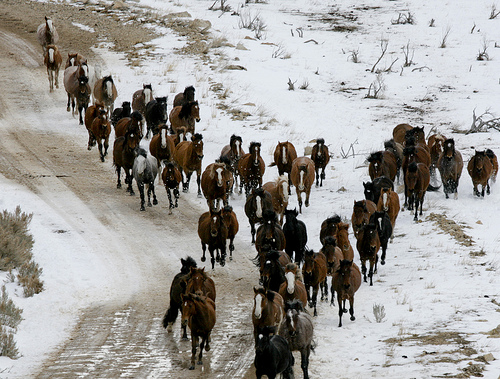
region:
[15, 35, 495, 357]
The horses are running in the snow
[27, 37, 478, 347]
The horses are frightened by something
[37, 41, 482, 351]
Many horses are running together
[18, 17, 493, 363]
The horses are ready to stampede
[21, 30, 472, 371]
Wild horses are running down a mountain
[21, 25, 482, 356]
Wild horses are in the snow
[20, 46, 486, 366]
Stallions and mares are running together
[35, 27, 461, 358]
Wild horses are running free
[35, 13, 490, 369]
Snow is covering the ground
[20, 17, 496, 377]
a herd of horses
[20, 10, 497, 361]
the horses are running in the snow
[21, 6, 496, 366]
a large herd of wild horses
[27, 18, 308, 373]
many of these horses have white faces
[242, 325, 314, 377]
this horse is black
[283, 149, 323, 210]
this horse is very fat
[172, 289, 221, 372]
this horse is brown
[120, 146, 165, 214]
this horse is ashen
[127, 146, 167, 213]
this horse is grey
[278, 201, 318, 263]
this horse is very black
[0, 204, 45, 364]
Scrubby bushes in snow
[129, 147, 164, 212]
Grey horse running with brown horses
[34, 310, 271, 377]
Muddy path worn by horse hooves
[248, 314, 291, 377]
Dark colored horse with white face spot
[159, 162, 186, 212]
Little brown horse running in snow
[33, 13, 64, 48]
Light colored horse at the rear of the group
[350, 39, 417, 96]
Dead branches in the snow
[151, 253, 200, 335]
Backwards facing horse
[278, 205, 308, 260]
Solid dark colored horse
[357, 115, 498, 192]
Small grouping of horses running in the snow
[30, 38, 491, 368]
Horses are running together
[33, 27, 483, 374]
Horses are in the snow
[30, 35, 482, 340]
Horses are frightened by something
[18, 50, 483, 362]
The horses are running fast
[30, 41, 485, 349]
Male and female horses are together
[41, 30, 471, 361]
Many horses are gathered together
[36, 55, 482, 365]
The horses are roaming free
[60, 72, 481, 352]
The horses are part of a herd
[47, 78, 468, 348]
The horses are following their leader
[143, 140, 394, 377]
these are several horses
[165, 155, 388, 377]
the horses are walking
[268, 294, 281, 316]
the horse is brown in color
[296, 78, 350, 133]
the ground is full of snow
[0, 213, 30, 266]
this is the grass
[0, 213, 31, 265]
the grass is brown in color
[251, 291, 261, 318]
the head is white in color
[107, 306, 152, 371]
the ground is brown in color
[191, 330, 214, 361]
these are the legs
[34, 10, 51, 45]
the horse is the last